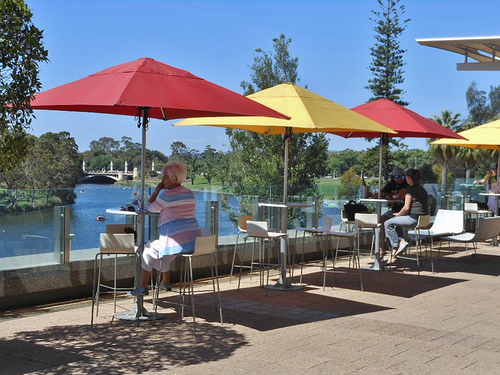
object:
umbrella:
[170, 80, 397, 136]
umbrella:
[431, 117, 499, 146]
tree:
[358, 0, 415, 228]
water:
[0, 174, 363, 259]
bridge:
[81, 151, 164, 183]